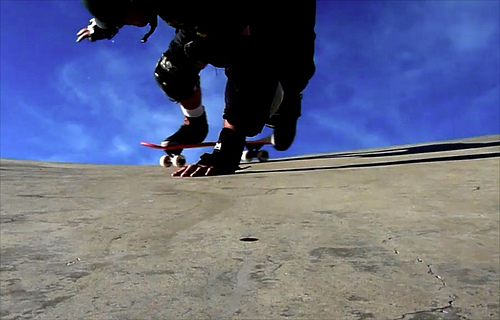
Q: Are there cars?
A: No, there are no cars.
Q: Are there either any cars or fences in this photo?
A: No, there are no cars or fences.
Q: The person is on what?
A: The person is on the skateboard.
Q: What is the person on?
A: The person is on the skateboard.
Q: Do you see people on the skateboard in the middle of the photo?
A: Yes, there is a person on the skateboard.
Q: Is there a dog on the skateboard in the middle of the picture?
A: No, there is a person on the skateboard.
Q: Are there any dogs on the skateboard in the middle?
A: No, there is a person on the skateboard.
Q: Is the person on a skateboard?
A: Yes, the person is on a skateboard.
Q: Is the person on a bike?
A: No, the person is on a skateboard.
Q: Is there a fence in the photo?
A: No, there are no fences.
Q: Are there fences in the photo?
A: No, there are no fences.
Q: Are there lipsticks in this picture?
A: No, there are no lipsticks.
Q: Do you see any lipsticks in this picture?
A: No, there are no lipsticks.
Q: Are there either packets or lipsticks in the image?
A: No, there are no lipsticks or packets.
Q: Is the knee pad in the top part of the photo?
A: Yes, the knee pad is in the top of the image.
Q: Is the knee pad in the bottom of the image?
A: No, the knee pad is in the top of the image.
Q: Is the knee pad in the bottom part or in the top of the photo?
A: The knee pad is in the top of the image.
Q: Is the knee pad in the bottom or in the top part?
A: The knee pad is in the top of the image.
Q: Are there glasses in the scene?
A: No, there are no glasses.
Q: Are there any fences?
A: No, there are no fences.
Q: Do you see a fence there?
A: No, there are no fences.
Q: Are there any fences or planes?
A: No, there are no fences or planes.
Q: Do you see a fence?
A: No, there are no fences.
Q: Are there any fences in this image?
A: No, there are no fences.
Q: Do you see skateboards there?
A: Yes, there is a skateboard.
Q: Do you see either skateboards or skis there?
A: Yes, there is a skateboard.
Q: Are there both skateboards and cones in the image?
A: No, there is a skateboard but no cones.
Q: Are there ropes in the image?
A: No, there are no ropes.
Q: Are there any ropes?
A: No, there are no ropes.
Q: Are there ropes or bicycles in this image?
A: No, there are no ropes or bicycles.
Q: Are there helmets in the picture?
A: Yes, there is a helmet.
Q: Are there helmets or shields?
A: Yes, there is a helmet.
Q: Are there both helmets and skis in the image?
A: No, there is a helmet but no skis.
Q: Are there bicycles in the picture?
A: No, there are no bicycles.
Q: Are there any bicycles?
A: No, there are no bicycles.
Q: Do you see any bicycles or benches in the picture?
A: No, there are no bicycles or benches.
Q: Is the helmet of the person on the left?
A: Yes, the helmet is on the left of the image.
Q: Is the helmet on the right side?
A: No, the helmet is on the left of the image.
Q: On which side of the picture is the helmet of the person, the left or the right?
A: The helmet is on the left of the image.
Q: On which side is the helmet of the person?
A: The helmet is on the left of the image.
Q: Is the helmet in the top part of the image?
A: Yes, the helmet is in the top of the image.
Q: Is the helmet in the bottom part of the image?
A: No, the helmet is in the top of the image.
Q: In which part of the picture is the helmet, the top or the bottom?
A: The helmet is in the top of the image.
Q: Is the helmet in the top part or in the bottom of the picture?
A: The helmet is in the top of the image.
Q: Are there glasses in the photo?
A: No, there are no glasses.